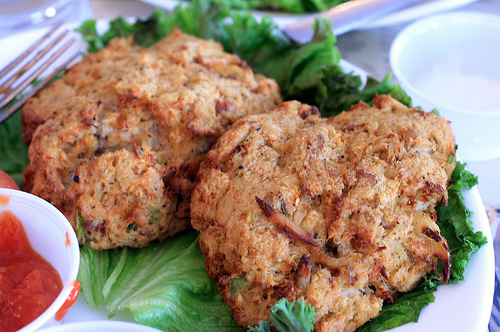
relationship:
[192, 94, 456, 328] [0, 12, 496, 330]
crabcake on plate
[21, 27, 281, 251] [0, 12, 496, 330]
crabcake on plate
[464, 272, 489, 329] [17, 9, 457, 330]
plate of food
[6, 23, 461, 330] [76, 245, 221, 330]
bib of lettuce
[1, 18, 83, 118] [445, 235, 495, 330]
fork on a plate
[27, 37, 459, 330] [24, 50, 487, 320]
meal on plate